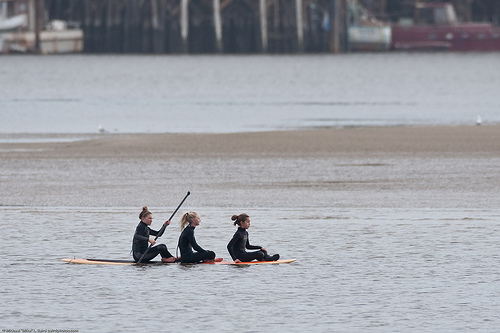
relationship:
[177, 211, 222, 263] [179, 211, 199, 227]
girl has blonde hair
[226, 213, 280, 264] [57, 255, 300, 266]
girl on board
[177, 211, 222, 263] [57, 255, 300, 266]
girl on board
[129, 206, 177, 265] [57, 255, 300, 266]
girls on board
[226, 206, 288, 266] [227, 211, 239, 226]
girl in pony tail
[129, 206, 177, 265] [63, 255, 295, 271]
girls sitting on board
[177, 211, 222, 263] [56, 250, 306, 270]
girl sitting on board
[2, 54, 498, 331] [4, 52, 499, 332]
choppy water in sea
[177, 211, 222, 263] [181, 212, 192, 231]
girl in a ponytail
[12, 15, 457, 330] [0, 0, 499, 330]
photo taken outdoors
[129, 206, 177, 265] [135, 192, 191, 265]
girls holding oar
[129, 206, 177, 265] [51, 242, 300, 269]
girls sitting on a board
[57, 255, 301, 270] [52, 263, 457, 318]
board in water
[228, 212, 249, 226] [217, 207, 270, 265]
hair on a girl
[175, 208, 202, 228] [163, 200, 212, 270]
hair on a girl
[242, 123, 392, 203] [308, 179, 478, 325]
sand between pools of water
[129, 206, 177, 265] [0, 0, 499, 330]
girls holds outdoors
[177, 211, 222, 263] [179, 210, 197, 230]
girl has hair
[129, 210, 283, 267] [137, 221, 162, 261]
girls wearing wet suit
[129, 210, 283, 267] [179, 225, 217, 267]
girls wearing wet suit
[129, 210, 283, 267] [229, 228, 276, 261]
girls wearing wet suit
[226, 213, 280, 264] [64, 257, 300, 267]
girl sitting on board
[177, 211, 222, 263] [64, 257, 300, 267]
girl sitting on board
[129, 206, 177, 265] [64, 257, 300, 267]
girls sitting on board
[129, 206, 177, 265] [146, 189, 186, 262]
girls holding oar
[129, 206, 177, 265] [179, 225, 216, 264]
girls wearing wet suit